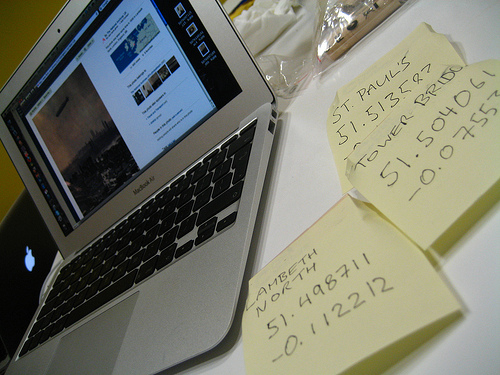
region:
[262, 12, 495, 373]
Yellow post it notes on table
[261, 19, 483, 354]
Notes have black writing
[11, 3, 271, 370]
Grey and black laptop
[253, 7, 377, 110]
Clear plastic wrapper by laptop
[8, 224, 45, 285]
Lit up apple on device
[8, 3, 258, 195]
The laptop has a lit up screen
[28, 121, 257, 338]
The laptop keys are black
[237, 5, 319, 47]
White napkin on table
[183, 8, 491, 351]
The table is white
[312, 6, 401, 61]
Brown object in wrapper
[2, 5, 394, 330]
a laptop computer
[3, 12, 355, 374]
a silver laptop computer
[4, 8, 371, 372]
a laptop on a table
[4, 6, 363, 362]
a table with a laptop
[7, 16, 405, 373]
a table with a silver laptop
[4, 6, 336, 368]
a laptop turned on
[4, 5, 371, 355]
a silver laptop turned on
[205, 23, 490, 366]
post it notes on the table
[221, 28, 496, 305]
three post it notes on the table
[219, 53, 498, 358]
yellow post it notes on the table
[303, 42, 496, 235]
Notes on the desk.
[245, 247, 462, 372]
Post it note on the desk.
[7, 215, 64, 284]
MAC logo on laptop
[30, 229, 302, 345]
Keyboard on the laptop.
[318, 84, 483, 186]
Words on the post it notes.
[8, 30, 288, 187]
Screen on the laptop.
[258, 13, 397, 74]
Plastic wrap on the table.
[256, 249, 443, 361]
Numbers on the paper.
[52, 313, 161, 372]
Mouse pad on the computer.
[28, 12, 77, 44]
Camera on the laptop.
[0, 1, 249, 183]
laptop screen is turned on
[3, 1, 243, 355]
the laptop is gray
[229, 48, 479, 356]
yellow sticky notes on counter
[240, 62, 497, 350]
black ink on notes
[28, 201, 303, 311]
black keyboard on laptop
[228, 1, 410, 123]
plastic bag behind laptop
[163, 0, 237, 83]
icons on the screen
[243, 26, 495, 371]
the table is white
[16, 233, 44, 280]
apple on laptop screen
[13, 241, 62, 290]
the apple is white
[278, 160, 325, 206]
a white table.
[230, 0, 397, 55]
a piece of plastic and material.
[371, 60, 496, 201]
a piece of paper with numbers.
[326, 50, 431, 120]
a yellow note says st.pauls.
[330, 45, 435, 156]
a note has the numbers 51513587.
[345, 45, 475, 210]
a note says tower bridge.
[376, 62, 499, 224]
a yellow note says 51.504061-0.07553.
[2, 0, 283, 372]
a laptop computer.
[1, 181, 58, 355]
a apple laptop.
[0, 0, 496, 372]
a table with two laptops.